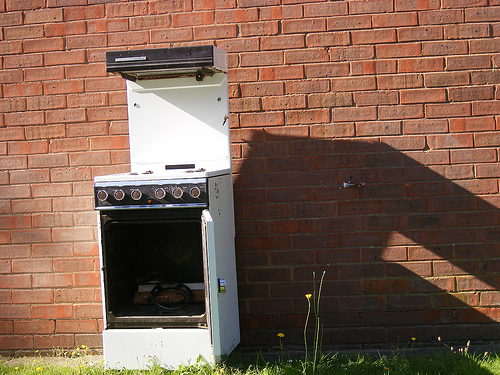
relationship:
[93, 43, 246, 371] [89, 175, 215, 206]
oven has dials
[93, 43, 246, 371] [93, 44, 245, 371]
oven has oven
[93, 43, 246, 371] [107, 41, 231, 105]
oven has stand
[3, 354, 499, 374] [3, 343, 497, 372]
grass on ground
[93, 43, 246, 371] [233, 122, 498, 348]
oven has shadow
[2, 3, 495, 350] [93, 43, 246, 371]
wall behind oven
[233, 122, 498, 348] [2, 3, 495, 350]
shadow on wall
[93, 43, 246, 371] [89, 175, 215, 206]
oven has knobs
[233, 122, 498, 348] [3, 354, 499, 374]
shadow on grass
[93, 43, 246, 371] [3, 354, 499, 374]
oven on top of grass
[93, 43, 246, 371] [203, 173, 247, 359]
oven has side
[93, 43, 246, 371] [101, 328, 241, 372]
oven has bottom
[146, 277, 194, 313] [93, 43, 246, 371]
cord inside oven